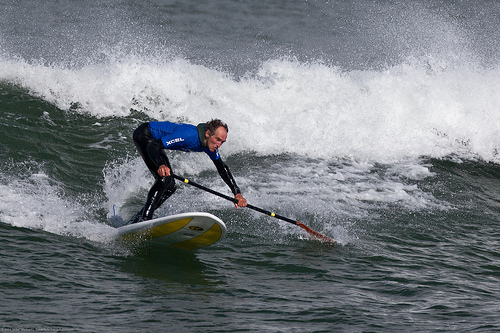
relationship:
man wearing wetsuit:
[129, 117, 247, 227] [125, 117, 248, 227]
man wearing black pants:
[129, 117, 247, 227] [125, 115, 178, 223]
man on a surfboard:
[129, 117, 247, 227] [111, 210, 228, 252]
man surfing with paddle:
[129, 117, 247, 227] [160, 172, 340, 257]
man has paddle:
[129, 117, 247, 227] [154, 165, 351, 251]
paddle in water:
[154, 165, 351, 251] [247, 65, 498, 331]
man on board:
[129, 112, 237, 220] [112, 210, 229, 252]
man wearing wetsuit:
[129, 117, 247, 227] [121, 110, 206, 216]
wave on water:
[1, 39, 498, 168] [1, 2, 498, 328]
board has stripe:
[115, 214, 227, 250] [186, 221, 221, 246]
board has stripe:
[115, 214, 227, 250] [122, 217, 192, 241]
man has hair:
[129, 117, 247, 227] [199, 119, 229, 134]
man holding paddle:
[129, 117, 247, 227] [162, 170, 337, 242]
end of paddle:
[283, 205, 343, 259] [169, 169, 343, 232]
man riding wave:
[129, 117, 247, 227] [234, 80, 498, 180]